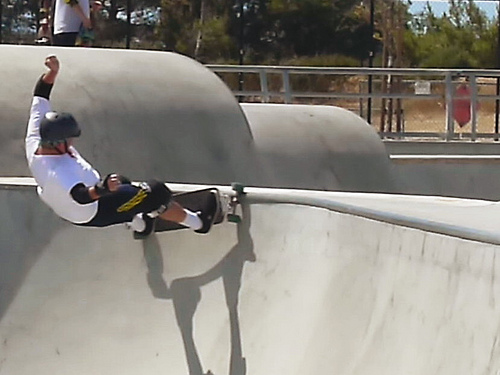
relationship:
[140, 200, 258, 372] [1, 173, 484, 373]
shadow casted on pike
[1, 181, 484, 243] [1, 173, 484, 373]
edge bordering pike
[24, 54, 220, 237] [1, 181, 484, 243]
guy skating on edge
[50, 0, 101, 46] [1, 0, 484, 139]
person standing in background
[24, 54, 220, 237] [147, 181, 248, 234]
guy doing tricks on skateboard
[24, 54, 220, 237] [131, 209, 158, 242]
guy wearing shoe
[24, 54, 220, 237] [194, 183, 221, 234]
guy wearing shoe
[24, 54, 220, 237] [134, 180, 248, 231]
guy on skateboard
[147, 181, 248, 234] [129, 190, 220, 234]
skateboard on feet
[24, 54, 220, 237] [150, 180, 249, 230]
guy on skateboard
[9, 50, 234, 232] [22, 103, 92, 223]
guy wearing shirt